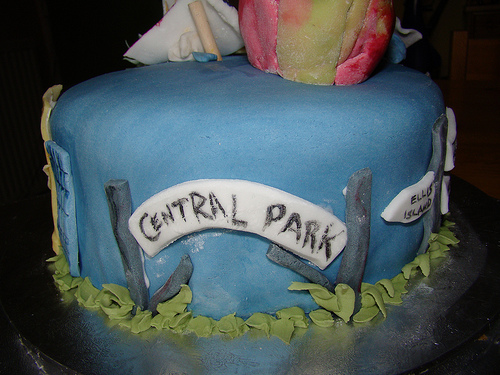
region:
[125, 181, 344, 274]
frosting sign reading central park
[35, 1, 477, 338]
white green and blue cake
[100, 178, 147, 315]
blue fondant on a cake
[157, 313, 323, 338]
green fondant leaves on a cake base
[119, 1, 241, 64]
white cloth on top of a cake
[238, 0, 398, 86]
red and yellow fondant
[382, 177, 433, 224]
white fondant sign for ellis island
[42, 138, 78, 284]
blue fondant rectangle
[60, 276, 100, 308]
green fondant leaves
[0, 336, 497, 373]
section of a metal tray on a table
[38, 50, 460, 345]
a blue edible cake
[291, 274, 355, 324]
green grass shaped frosting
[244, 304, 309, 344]
green grass shaped frosting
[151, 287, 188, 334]
green grass shaped frosting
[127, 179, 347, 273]
a frosting sign reading CENTRAL PARK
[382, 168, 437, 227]
a white frosting sign reading ELLIS ISLAND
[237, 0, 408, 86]
a large pink and green piece of frosting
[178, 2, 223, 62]
a short wooden stick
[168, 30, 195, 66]
a white piece of frosting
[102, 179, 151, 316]
a black piece of frosting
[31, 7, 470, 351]
birthday cake with fondant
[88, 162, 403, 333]
central park sign made with fondant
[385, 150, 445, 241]
sign for ellis island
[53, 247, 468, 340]
grassy cak border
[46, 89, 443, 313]
primarily blue cake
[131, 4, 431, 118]
red, yellow, and white toppings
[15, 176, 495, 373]
silver platter for cake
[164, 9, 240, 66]
wooden stick holding up cake topper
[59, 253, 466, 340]
green icing on bottom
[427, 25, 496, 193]
back of wooden chair in background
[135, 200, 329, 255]
the words are black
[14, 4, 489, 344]
the cake is blue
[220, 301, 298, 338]
the frosting looks like grass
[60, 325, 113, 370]
the cake pan is black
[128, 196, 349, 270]
the sign is white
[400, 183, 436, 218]
ellis island is written in black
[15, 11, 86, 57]
the background is black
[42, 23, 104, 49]
the background is black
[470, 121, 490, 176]
the table is wooden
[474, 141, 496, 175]
the table is brown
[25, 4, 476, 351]
s cake color blue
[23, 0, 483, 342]
base of cake has green leaves decorations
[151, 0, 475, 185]
cake has decorations on top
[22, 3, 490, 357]
cahe is over a black table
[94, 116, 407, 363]
letters on cake says "Central Park"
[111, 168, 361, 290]
letters on a cake are black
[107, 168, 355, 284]
black letters are on a white surface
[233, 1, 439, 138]
decoration on a cake is yellow and red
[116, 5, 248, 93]
a white decoration on a cake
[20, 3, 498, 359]
blue cake has green, white and red decorations